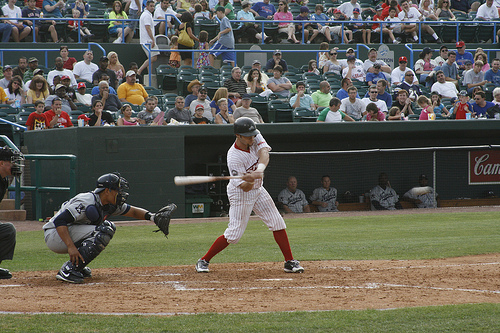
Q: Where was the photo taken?
A: Baseball Game.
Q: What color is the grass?
A: Green.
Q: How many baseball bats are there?
A: One.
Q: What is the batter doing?
A: Hitting the ball.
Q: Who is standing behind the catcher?
A: The Umpire.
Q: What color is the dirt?
A: Tan.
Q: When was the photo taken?
A: Daytime.